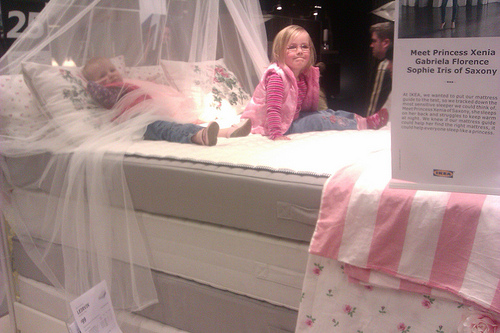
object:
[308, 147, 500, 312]
blanket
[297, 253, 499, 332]
blanket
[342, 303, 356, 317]
flowers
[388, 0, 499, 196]
sign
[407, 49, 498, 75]
text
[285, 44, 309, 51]
glasses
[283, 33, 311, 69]
face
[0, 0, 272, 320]
canopy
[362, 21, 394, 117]
side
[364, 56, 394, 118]
jacket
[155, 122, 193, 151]
number 25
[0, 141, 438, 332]
pile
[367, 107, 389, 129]
shoes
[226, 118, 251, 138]
shoe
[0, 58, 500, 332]
bed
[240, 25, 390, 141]
child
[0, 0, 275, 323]
fabric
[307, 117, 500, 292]
fabric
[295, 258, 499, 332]
fabric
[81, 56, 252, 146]
baby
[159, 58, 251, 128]
pillow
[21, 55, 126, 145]
pillow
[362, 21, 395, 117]
man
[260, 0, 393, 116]
back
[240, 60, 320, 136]
jacket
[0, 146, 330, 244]
mattresses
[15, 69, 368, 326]
bed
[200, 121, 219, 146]
shoe